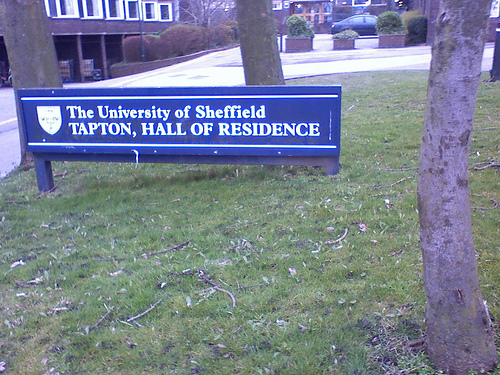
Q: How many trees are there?
A: Three.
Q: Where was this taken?
A: University of Sheffield.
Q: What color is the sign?
A: Blue.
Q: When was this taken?
A: Daytime.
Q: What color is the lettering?
A: White.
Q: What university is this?
A: Sheffield.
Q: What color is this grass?
A: Green.